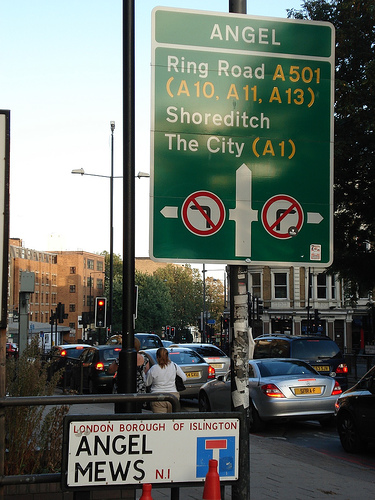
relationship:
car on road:
[196, 356, 343, 433] [40, 346, 373, 467]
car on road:
[335, 365, 374, 459] [40, 346, 373, 467]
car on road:
[112, 348, 216, 401] [40, 346, 373, 467]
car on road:
[253, 333, 349, 392] [40, 346, 373, 467]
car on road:
[64, 346, 134, 389] [40, 346, 373, 467]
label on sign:
[164, 53, 320, 164] [148, 4, 338, 270]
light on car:
[260, 383, 286, 398] [196, 356, 343, 433]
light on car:
[255, 376, 316, 395] [188, 354, 344, 420]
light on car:
[95, 363, 102, 373] [69, 343, 118, 390]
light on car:
[332, 380, 343, 396] [196, 356, 343, 433]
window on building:
[270, 270, 289, 299] [241, 259, 374, 354]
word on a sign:
[202, 20, 281, 63] [148, 4, 338, 270]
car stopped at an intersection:
[198, 357, 342, 434] [46, 296, 227, 348]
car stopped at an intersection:
[252, 334, 349, 382] [46, 296, 227, 348]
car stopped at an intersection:
[139, 347, 211, 396] [46, 296, 227, 348]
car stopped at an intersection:
[173, 341, 228, 374] [46, 296, 227, 348]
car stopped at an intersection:
[79, 347, 118, 390] [46, 296, 227, 348]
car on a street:
[198, 357, 342, 434] [297, 423, 346, 456]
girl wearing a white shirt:
[139, 337, 194, 420] [133, 361, 202, 396]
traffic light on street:
[92, 293, 109, 331] [67, 336, 352, 443]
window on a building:
[271, 269, 291, 300] [235, 266, 374, 354]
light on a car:
[325, 378, 344, 397] [329, 380, 341, 396]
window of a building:
[87, 258, 93, 268] [2, 237, 105, 341]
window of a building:
[97, 260, 103, 269] [2, 237, 105, 341]